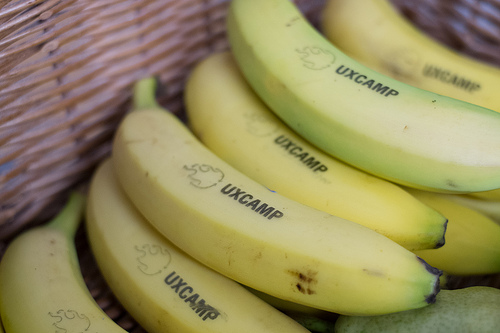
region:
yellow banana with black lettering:
[109, 67, 456, 313]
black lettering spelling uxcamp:
[181, 150, 295, 237]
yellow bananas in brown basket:
[8, 0, 494, 318]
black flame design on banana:
[182, 157, 224, 192]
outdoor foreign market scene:
[2, 7, 497, 332]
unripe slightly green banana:
[206, 0, 496, 193]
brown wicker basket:
[2, 0, 496, 327]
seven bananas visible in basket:
[4, 0, 496, 325]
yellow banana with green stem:
[111, 67, 467, 314]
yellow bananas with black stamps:
[3, 1, 496, 323]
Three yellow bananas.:
[7, 125, 274, 331]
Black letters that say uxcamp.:
[214, 175, 282, 235]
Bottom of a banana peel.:
[353, 245, 450, 331]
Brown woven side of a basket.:
[0, 27, 187, 111]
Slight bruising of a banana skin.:
[269, 257, 363, 300]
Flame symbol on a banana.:
[151, 153, 235, 225]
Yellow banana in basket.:
[1, 197, 109, 330]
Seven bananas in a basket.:
[6, 56, 497, 318]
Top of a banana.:
[69, 51, 181, 158]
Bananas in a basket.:
[0, 32, 423, 197]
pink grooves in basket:
[9, 59, 94, 101]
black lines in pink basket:
[29, 15, 99, 140]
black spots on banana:
[287, 266, 328, 295]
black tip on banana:
[421, 253, 438, 272]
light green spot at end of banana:
[410, 264, 431, 306]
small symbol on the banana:
[185, 157, 222, 192]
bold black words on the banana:
[260, 123, 338, 190]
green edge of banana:
[125, 65, 168, 120]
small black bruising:
[370, 32, 422, 80]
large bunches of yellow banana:
[94, 56, 443, 331]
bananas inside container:
[36, 26, 471, 306]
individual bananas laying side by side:
[40, 25, 445, 320]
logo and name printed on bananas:
[180, 141, 295, 226]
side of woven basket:
[10, 15, 245, 180]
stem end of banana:
[95, 55, 175, 115]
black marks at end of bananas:
[415, 200, 455, 305]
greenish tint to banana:
[241, 25, 481, 150]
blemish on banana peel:
[242, 230, 342, 297]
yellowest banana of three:
[205, 65, 426, 246]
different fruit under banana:
[310, 246, 497, 328]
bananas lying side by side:
[10, 1, 496, 321]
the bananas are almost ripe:
[2, 0, 493, 331]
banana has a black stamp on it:
[120, 76, 441, 313]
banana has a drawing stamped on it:
[130, 236, 175, 274]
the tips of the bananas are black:
[417, 205, 449, 310]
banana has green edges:
[230, 5, 498, 196]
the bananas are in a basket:
[6, 0, 497, 330]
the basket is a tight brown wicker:
[1, 0, 496, 331]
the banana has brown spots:
[290, 260, 323, 300]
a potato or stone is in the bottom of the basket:
[333, 281, 498, 331]